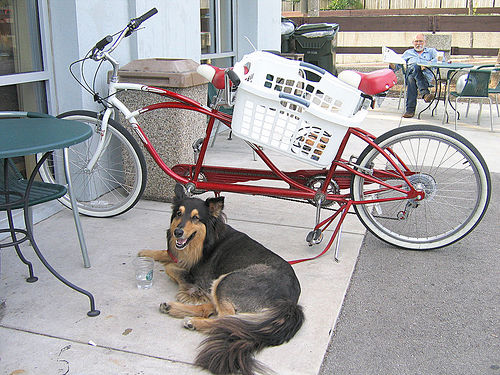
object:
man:
[389, 34, 446, 117]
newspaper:
[382, 42, 407, 65]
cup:
[132, 256, 155, 289]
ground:
[0, 55, 500, 374]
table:
[417, 61, 474, 123]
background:
[368, 46, 496, 128]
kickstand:
[334, 200, 352, 261]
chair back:
[461, 69, 491, 96]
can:
[291, 22, 340, 81]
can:
[281, 17, 297, 53]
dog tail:
[192, 305, 305, 374]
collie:
[137, 182, 305, 362]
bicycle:
[34, 6, 493, 262]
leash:
[288, 200, 351, 264]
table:
[0, 117, 100, 316]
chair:
[0, 106, 91, 268]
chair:
[442, 69, 493, 132]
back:
[462, 56, 482, 101]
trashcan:
[106, 57, 211, 203]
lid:
[107, 58, 209, 88]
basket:
[232, 50, 376, 168]